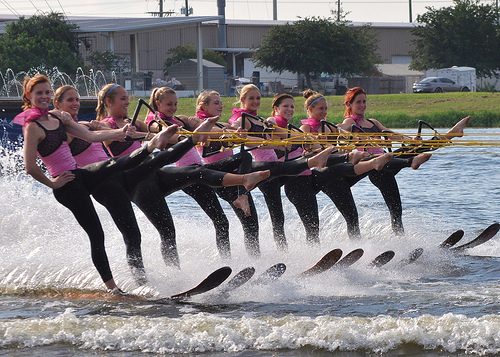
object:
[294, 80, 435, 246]
performers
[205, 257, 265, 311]
waterskis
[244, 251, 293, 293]
waterskis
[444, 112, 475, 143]
foot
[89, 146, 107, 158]
pink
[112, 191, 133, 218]
black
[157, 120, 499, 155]
rope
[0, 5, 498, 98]
building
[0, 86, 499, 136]
shore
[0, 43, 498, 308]
tricks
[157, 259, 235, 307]
waterskis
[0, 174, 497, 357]
water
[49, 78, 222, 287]
girls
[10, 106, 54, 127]
scarves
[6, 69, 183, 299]
girl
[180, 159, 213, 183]
knee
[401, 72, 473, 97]
car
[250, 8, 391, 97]
tree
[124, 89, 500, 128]
grass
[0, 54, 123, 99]
fountain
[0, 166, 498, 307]
big splash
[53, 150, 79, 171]
pink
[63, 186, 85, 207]
black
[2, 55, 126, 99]
water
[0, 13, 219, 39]
cover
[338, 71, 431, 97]
fence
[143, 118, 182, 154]
feet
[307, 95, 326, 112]
headband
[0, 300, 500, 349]
wake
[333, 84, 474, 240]
woman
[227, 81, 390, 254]
woman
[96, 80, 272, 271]
woman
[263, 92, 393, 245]
woman